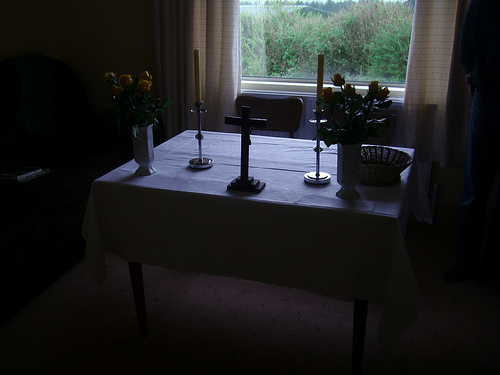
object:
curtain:
[184, 0, 243, 131]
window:
[236, 0, 408, 89]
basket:
[314, 207, 367, 247]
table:
[80, 130, 432, 353]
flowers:
[224, 121, 285, 179]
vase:
[131, 126, 155, 181]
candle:
[191, 47, 204, 101]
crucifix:
[219, 103, 270, 197]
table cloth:
[78, 125, 427, 337]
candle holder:
[190, 102, 214, 170]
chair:
[232, 149, 305, 197]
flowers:
[317, 80, 400, 148]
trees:
[249, 0, 416, 84]